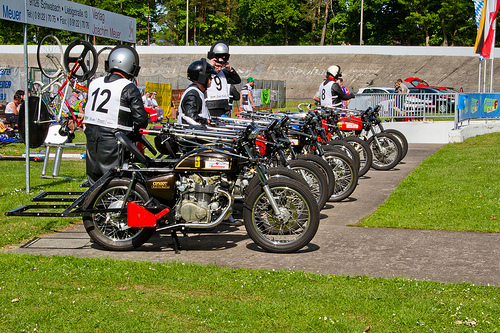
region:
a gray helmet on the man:
[99, 40, 147, 81]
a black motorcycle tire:
[80, 171, 160, 264]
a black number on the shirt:
[87, 81, 119, 119]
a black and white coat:
[74, 71, 160, 135]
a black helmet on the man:
[182, 60, 222, 87]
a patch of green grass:
[342, 123, 498, 248]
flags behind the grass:
[467, 0, 498, 62]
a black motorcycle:
[61, 119, 325, 264]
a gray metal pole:
[14, 16, 33, 202]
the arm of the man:
[120, 83, 150, 134]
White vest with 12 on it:
[85, 74, 133, 136]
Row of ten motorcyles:
[141, 102, 412, 235]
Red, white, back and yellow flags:
[470, 20, 499, 65]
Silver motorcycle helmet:
[104, 41, 139, 79]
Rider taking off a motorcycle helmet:
[204, 38, 245, 114]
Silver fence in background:
[366, 87, 458, 127]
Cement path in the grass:
[358, 219, 496, 309]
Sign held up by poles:
[1, 1, 165, 50]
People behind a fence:
[384, 74, 417, 127]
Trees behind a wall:
[189, 8, 372, 57]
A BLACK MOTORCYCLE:
[81, 128, 325, 256]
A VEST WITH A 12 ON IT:
[69, 70, 145, 137]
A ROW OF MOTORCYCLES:
[56, 99, 425, 264]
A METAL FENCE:
[361, 87, 466, 124]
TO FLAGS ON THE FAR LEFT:
[461, 4, 498, 90]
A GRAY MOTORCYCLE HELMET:
[101, 41, 148, 81]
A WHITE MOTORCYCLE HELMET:
[311, 62, 364, 89]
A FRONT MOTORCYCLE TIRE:
[234, 174, 339, 256]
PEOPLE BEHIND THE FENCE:
[387, 76, 419, 106]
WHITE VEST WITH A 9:
[199, 70, 239, 107]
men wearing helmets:
[55, 36, 381, 165]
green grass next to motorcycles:
[117, 272, 222, 331]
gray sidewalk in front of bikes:
[353, 191, 483, 296]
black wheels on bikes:
[248, 163, 324, 251]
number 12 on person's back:
[80, 74, 132, 127]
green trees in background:
[338, 5, 425, 43]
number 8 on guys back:
[301, 64, 353, 127]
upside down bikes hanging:
[17, 33, 92, 130]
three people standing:
[91, 46, 258, 157]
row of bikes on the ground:
[196, 111, 426, 253]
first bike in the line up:
[82, 130, 320, 252]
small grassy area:
[2, 257, 289, 329]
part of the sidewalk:
[345, 217, 498, 271]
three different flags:
[474, 0, 499, 90]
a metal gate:
[352, 92, 454, 117]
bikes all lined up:
[85, 99, 411, 253]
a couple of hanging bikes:
[32, 27, 86, 147]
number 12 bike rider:
[82, 44, 145, 224]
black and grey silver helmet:
[106, 42, 139, 74]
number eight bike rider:
[315, 65, 352, 112]